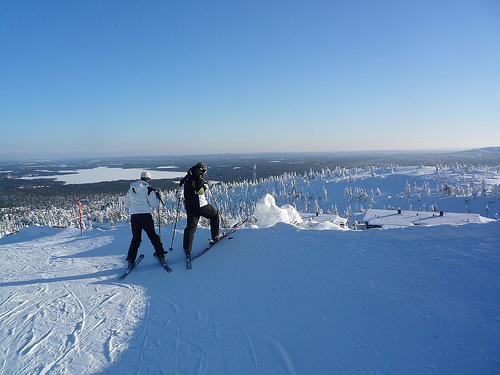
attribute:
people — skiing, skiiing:
[126, 160, 223, 258]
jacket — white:
[125, 178, 165, 216]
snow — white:
[104, 291, 499, 374]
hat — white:
[138, 169, 151, 180]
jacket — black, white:
[178, 174, 215, 206]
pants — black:
[126, 214, 166, 256]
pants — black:
[182, 206, 221, 255]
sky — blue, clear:
[5, 3, 493, 81]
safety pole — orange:
[76, 205, 84, 238]